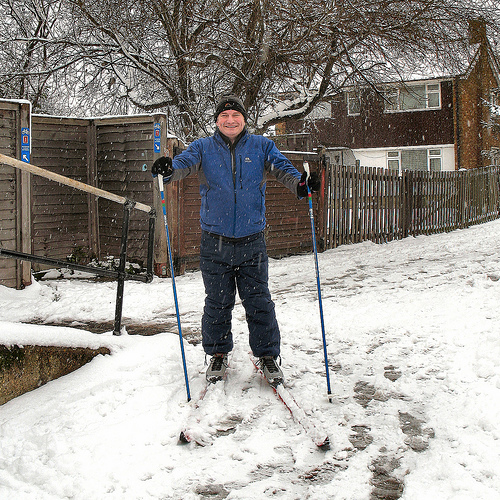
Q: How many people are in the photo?
A: One.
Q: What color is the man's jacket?
A: Blue.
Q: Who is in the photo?
A: A man.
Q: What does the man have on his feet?
A: Skies.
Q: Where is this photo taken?
A: In a backyard.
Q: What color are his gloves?
A: Black.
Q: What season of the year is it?
A: Winter.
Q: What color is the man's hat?
A: Black.